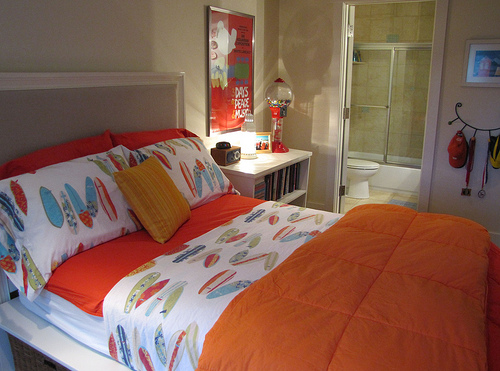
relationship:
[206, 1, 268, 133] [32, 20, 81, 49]
poster on wall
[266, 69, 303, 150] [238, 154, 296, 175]
machine on shelves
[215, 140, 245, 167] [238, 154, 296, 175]
radio on shelves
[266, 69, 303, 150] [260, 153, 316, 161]
machine on table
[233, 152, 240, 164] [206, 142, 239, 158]
time on clock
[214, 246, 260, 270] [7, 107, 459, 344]
sheets on bed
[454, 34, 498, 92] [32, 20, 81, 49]
picture on wall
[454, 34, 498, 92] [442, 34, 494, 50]
picture in frame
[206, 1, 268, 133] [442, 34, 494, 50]
poster in frame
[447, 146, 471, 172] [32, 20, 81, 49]
hat on wall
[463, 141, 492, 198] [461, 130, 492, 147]
metal on ribbon